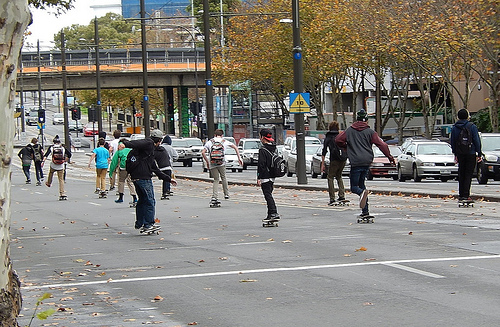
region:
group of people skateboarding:
[15, 102, 495, 242]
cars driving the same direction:
[70, 120, 495, 180]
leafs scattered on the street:
[11, 155, 496, 321]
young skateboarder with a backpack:
[250, 121, 287, 226]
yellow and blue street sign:
[285, 86, 315, 116]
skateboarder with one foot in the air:
[36, 130, 73, 200]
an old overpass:
[0, 40, 295, 90]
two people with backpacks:
[196, 125, 286, 230]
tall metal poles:
[30, 37, 330, 182]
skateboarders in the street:
[18, 104, 485, 236]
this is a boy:
[252, 121, 283, 216]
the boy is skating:
[254, 123, 288, 225]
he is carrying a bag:
[266, 150, 285, 179]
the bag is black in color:
[267, 150, 285, 179]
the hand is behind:
[117, 125, 147, 148]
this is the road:
[220, 244, 332, 324]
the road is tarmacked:
[215, 228, 319, 323]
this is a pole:
[288, 25, 311, 87]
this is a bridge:
[105, 44, 138, 85]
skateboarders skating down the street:
[25, 106, 485, 245]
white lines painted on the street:
[21, 243, 495, 313]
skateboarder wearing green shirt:
[108, 133, 133, 205]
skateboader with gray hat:
[122, 122, 174, 239]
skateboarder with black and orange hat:
[254, 127, 288, 229]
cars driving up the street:
[37, 99, 499, 179]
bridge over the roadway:
[22, 41, 223, 87]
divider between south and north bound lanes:
[140, 144, 497, 200]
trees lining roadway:
[217, 4, 486, 129]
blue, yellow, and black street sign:
[285, 90, 310, 117]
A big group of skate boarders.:
[16, 104, 496, 235]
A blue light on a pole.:
[196, 73, 223, 92]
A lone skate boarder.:
[441, 95, 494, 208]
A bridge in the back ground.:
[15, 36, 247, 96]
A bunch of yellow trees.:
[236, 33, 496, 130]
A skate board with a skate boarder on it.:
[258, 209, 280, 232]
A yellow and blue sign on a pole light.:
[280, 85, 315, 118]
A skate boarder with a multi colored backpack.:
[197, 122, 249, 202]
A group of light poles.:
[50, 35, 323, 142]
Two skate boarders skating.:
[301, 113, 405, 229]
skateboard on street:
[259, 215, 281, 230]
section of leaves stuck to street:
[12, 256, 173, 320]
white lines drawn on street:
[18, 250, 498, 312]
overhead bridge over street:
[12, 47, 232, 99]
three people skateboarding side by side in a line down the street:
[121, 106, 403, 239]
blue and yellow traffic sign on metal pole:
[282, 87, 319, 116]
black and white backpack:
[257, 143, 289, 175]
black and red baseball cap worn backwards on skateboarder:
[256, 124, 276, 146]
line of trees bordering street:
[212, 0, 497, 135]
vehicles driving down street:
[145, 131, 498, 186]